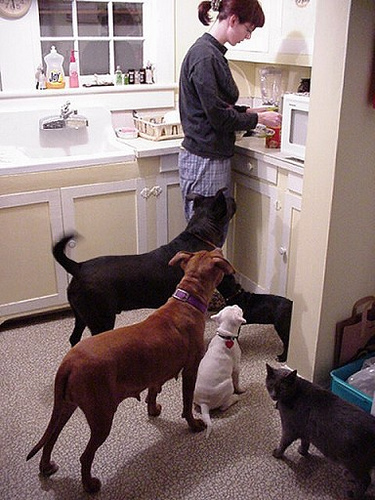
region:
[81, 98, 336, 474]
hungry animals waiting for food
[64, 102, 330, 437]
hungry pets waiting for food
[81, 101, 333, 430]
hungry dogs and cat waiting for food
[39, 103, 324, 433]
eager animals waiting for food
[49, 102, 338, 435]
eager pets waiting for food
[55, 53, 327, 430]
eager dogs and cat waiting for food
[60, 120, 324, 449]
excited pets waiting for food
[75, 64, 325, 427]
alert pets waiting for food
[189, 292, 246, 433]
cute white dog sitting on floor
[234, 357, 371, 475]
cute dark cat on floor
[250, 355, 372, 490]
One cat in the corner.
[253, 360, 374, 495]
The cat is grey.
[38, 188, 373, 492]
Four dogs and one cat.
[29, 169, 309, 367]
Two dogs are black.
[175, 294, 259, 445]
One dog is white.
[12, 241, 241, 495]
One dog is brown.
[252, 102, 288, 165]
A can of food.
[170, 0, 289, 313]
A person opening a can.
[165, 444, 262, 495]
The floor is white and speckled.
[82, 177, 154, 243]
The cabinets are white and yellow.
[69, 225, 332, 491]
Animals are standing in kitchen.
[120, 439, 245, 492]
Floor is grey color.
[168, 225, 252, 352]
Dogs have colllar in neck.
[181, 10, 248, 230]
Woman is standing in kitchen.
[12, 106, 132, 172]
Sink is white color.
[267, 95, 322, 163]
Microwave is white color.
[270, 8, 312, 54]
Cupboards are white color.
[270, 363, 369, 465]
Cat is black color.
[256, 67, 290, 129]
Blender is in kitchen counter.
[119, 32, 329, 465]
woman with dogs and cat in kitchen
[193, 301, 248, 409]
small white dog is sitting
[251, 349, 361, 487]
large grey cat is looking at the camera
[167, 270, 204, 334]
brown dog has purple collar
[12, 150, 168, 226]
kitchen cabinets are beige and white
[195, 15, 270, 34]
woman wearing glasses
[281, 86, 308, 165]
white microwave on countertop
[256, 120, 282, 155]
woman opening canned dog food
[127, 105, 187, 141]
dish drainer behind woman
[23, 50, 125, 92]
white windowsill with liquid soaps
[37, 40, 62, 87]
Nearly empty Joy dishsoap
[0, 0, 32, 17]
Lower part of white clock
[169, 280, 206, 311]
Purple dog collar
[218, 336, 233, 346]
Red heart dog tag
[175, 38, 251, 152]
Long sleeve blue sweater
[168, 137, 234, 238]
Blue plaid pajama pants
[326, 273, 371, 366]
Grocery bag folded against wall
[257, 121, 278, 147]
Red dog food can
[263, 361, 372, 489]
Grey cat looking at camera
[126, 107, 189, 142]
Rack for drying dishes